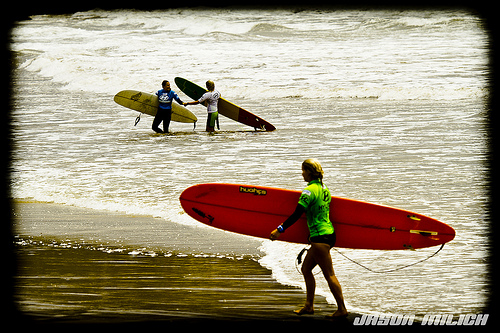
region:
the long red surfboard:
[177, 181, 455, 248]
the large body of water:
[16, 14, 493, 315]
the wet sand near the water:
[16, 198, 339, 320]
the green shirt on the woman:
[298, 178, 335, 234]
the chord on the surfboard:
[294, 237, 451, 274]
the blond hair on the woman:
[298, 156, 330, 193]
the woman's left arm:
[270, 186, 306, 241]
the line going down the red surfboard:
[175, 191, 456, 239]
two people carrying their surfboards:
[115, 75, 277, 137]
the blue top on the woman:
[155, 90, 185, 110]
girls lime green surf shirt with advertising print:
[288, 179, 350, 261]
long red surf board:
[165, 164, 485, 257]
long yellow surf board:
[106, 84, 203, 140]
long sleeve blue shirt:
[152, 80, 182, 120]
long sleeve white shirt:
[194, 86, 230, 121]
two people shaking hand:
[150, 74, 226, 143]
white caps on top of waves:
[200, 14, 482, 71]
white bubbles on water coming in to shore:
[351, 112, 474, 202]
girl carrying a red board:
[257, 142, 375, 322]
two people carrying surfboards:
[112, 48, 307, 140]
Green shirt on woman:
[292, 182, 341, 239]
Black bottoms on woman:
[300, 230, 342, 252]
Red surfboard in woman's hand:
[170, 177, 462, 269]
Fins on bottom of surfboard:
[397, 208, 446, 258]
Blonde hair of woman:
[297, 153, 331, 193]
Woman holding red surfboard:
[264, 152, 350, 321]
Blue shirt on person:
[153, 82, 180, 112]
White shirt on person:
[193, 88, 223, 115]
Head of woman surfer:
[296, 154, 328, 187]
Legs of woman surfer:
[287, 242, 352, 308]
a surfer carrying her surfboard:
[171, 142, 489, 329]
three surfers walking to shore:
[94, 33, 489, 324]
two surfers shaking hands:
[93, 41, 282, 151]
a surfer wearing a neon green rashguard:
[264, 134, 366, 330]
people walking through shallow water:
[94, 66, 426, 330]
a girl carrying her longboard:
[173, 140, 477, 330]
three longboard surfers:
[108, 63, 494, 319]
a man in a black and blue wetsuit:
[116, 78, 197, 150]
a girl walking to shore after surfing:
[172, 158, 474, 325]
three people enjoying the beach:
[100, 52, 499, 329]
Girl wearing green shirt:
[279, 153, 339, 276]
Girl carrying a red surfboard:
[183, 154, 433, 301]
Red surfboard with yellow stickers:
[171, 165, 448, 277]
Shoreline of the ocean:
[59, 224, 285, 277]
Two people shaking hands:
[155, 75, 237, 136]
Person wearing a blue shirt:
[101, 75, 191, 145]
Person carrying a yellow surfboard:
[102, 70, 180, 135]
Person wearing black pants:
[145, 75, 180, 142]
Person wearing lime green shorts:
[198, 78, 238, 140]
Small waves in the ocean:
[209, 20, 351, 52]